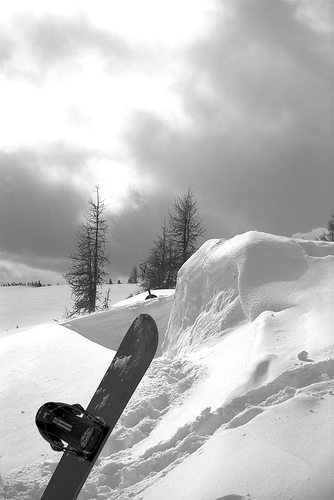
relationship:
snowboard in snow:
[32, 309, 162, 494] [8, 223, 333, 494]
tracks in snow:
[5, 334, 331, 489] [8, 223, 333, 494]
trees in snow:
[62, 183, 110, 320] [8, 223, 333, 494]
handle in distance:
[142, 280, 164, 301] [9, 223, 327, 341]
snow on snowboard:
[0, 223, 334, 500] [32, 309, 162, 494]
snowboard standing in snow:
[32, 309, 162, 494] [8, 223, 333, 494]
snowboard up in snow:
[32, 309, 162, 494] [8, 223, 333, 494]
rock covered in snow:
[165, 212, 328, 349] [8, 223, 333, 494]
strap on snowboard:
[36, 397, 107, 463] [32, 309, 162, 494]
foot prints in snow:
[1, 329, 333, 496] [8, 223, 333, 494]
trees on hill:
[62, 186, 201, 319] [162, 230, 334, 347]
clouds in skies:
[12, 0, 333, 255] [0, 0, 331, 272]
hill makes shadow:
[161, 220, 333, 348] [65, 289, 175, 354]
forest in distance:
[9, 267, 197, 285] [9, 223, 327, 341]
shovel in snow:
[142, 288, 160, 305] [8, 223, 333, 494]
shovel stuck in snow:
[142, 288, 160, 305] [8, 223, 333, 494]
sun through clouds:
[11, 0, 238, 217] [12, 0, 333, 255]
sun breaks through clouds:
[11, 0, 238, 217] [12, 0, 333, 255]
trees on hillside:
[62, 186, 201, 319] [9, 223, 327, 341]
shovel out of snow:
[142, 288, 160, 305] [8, 223, 333, 494]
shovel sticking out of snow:
[142, 288, 160, 305] [8, 223, 333, 494]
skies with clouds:
[0, 0, 331, 272] [12, 0, 333, 255]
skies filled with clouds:
[0, 0, 331, 272] [12, 0, 333, 255]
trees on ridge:
[62, 186, 201, 319] [12, 224, 333, 325]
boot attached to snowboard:
[31, 397, 106, 465] [32, 309, 162, 494]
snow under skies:
[8, 223, 333, 494] [0, 0, 331, 272]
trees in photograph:
[62, 186, 201, 319] [8, 3, 332, 492]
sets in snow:
[3, 335, 332, 499] [8, 223, 333, 494]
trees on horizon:
[3, 267, 191, 291] [5, 216, 332, 326]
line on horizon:
[2, 264, 173, 289] [5, 216, 332, 326]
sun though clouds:
[11, 0, 238, 217] [12, 0, 333, 255]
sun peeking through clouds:
[11, 0, 238, 217] [12, 0, 333, 255]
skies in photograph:
[13, 1, 331, 270] [8, 3, 332, 492]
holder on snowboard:
[34, 390, 107, 461] [32, 309, 162, 494]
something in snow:
[32, 308, 166, 496] [8, 223, 333, 494]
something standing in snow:
[32, 308, 166, 496] [8, 223, 333, 494]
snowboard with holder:
[32, 309, 162, 494] [34, 390, 107, 461]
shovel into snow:
[142, 288, 160, 305] [8, 223, 333, 494]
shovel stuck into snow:
[142, 288, 160, 305] [8, 223, 333, 494]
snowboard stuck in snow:
[32, 309, 162, 494] [8, 223, 333, 494]